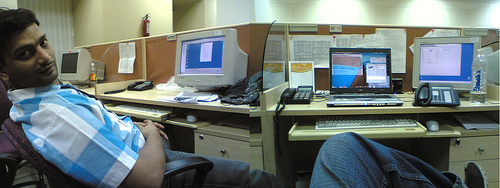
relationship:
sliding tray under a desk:
[290, 125, 458, 142] [115, 80, 200, 106]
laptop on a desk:
[326, 47, 404, 105] [261, 19, 498, 186]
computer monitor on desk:
[171, 28, 249, 91] [105, 68, 265, 163]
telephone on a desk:
[275, 85, 314, 105] [269, 76, 499, 168]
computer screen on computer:
[55, 50, 80, 81] [56, 45, 109, 92]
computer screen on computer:
[181, 37, 225, 74] [168, 23, 255, 122]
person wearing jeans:
[306, 130, 496, 184] [238, 100, 434, 186]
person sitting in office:
[0, 6, 289, 188] [5, 5, 483, 183]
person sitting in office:
[10, 22, 98, 138] [5, 5, 483, 183]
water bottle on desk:
[463, 40, 495, 106] [265, 84, 483, 127]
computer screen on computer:
[408, 40, 485, 84] [413, 37, 482, 91]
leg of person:
[305, 131, 461, 187] [1, 8, 483, 187]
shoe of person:
[465, 162, 490, 187] [1, 8, 483, 187]